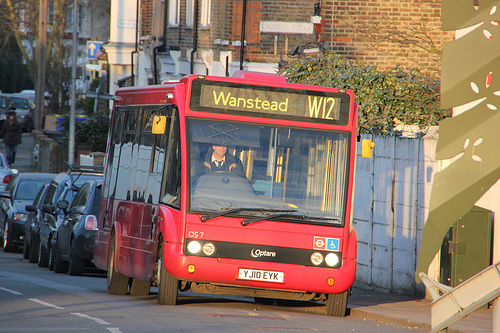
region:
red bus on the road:
[90, 58, 360, 315]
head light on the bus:
[187, 240, 202, 256]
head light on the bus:
[205, 242, 220, 255]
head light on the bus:
[305, 246, 322, 263]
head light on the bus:
[329, 250, 339, 273]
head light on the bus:
[318, 272, 333, 288]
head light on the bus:
[183, 260, 197, 277]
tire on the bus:
[152, 262, 183, 308]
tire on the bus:
[125, 273, 152, 299]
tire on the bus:
[310, 292, 357, 318]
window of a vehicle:
[187, 115, 252, 210]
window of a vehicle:
[265, 120, 352, 234]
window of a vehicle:
[165, 112, 193, 207]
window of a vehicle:
[134, 110, 157, 195]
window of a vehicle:
[120, 133, 148, 188]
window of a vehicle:
[107, 145, 130, 184]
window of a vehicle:
[75, 191, 93, 206]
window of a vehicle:
[38, 184, 57, 206]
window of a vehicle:
[17, 180, 40, 198]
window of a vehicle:
[4, 175, 20, 192]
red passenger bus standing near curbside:
[94, 72, 357, 317]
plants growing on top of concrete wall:
[276, 52, 444, 140]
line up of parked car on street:
[3, 168, 108, 273]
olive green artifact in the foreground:
[428, 4, 499, 272]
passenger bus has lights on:
[168, 224, 350, 282]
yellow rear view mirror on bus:
[148, 109, 169, 140]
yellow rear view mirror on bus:
[358, 134, 376, 161]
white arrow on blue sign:
[85, 35, 100, 63]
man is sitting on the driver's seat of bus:
[185, 124, 257, 200]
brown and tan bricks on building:
[325, 5, 440, 77]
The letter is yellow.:
[301, 86, 324, 122]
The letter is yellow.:
[276, 90, 294, 115]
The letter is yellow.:
[268, 93, 279, 116]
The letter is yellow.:
[259, 93, 272, 113]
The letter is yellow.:
[251, 90, 261, 115]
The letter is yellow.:
[244, 90, 256, 112]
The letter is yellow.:
[233, 90, 248, 111]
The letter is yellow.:
[226, 94, 238, 109]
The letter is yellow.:
[205, 83, 231, 110]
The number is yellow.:
[318, 91, 335, 124]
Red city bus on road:
[87, 68, 358, 318]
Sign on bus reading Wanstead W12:
[194, 78, 341, 125]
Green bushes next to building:
[354, 63, 437, 140]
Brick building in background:
[135, 1, 295, 77]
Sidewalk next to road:
[352, 277, 435, 330]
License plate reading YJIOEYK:
[235, 264, 283, 286]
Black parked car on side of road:
[50, 173, 102, 275]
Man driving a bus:
[192, 136, 249, 194]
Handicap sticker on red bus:
[324, 236, 341, 251]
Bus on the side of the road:
[95, 75, 360, 318]